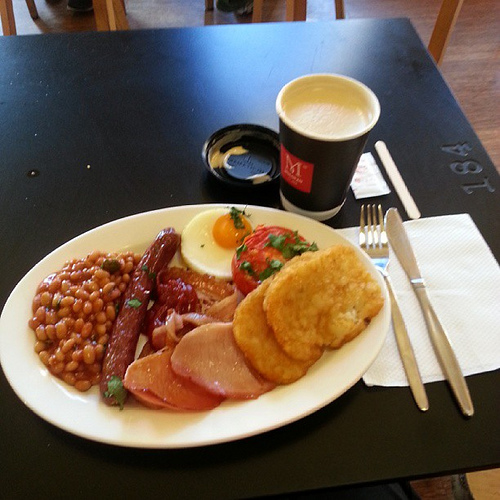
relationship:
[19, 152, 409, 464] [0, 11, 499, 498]
plate on table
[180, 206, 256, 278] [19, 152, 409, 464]
egg on plate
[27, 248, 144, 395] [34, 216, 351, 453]
beans on a plate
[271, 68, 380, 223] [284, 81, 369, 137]
cup of coffee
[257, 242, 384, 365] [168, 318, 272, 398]
hash brown and ham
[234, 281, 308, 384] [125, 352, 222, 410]
hash brown and ham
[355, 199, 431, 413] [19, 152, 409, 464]
fork next to plate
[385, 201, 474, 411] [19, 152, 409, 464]
knife next to plate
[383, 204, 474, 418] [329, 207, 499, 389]
butter knife on napkin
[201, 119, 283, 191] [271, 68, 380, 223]
lid by cup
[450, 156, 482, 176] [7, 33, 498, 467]
8 on table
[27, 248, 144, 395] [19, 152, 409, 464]
beans on plate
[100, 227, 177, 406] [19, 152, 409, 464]
sausage on plate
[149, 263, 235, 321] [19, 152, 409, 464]
bacon on plate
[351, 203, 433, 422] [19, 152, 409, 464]
fork next to plate